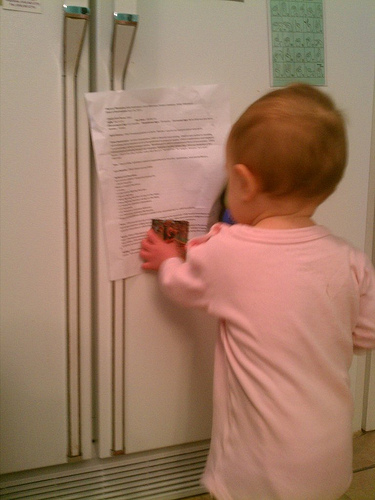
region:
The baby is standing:
[193, 141, 368, 462]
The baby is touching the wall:
[147, 199, 254, 294]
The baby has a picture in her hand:
[145, 218, 181, 263]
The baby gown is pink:
[265, 296, 338, 431]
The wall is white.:
[13, 245, 45, 434]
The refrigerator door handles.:
[57, 7, 149, 49]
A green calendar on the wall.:
[265, 14, 334, 90]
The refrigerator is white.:
[20, 124, 95, 342]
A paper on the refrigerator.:
[74, 95, 224, 222]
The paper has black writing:
[118, 105, 218, 169]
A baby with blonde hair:
[228, 102, 360, 222]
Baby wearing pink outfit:
[162, 228, 372, 437]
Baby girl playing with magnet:
[136, 75, 373, 422]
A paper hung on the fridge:
[80, 101, 208, 279]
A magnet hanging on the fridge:
[130, 165, 209, 279]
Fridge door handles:
[55, 13, 127, 313]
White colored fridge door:
[3, 295, 170, 445]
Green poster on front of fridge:
[269, 2, 334, 87]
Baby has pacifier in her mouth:
[206, 165, 247, 228]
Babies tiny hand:
[131, 226, 208, 309]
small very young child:
[162, 72, 373, 492]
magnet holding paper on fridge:
[144, 201, 201, 267]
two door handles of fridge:
[56, 0, 140, 108]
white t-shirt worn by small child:
[177, 225, 374, 497]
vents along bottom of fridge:
[66, 413, 214, 499]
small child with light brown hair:
[219, 79, 356, 219]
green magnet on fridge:
[265, 0, 339, 88]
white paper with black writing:
[86, 80, 242, 290]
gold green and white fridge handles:
[59, 2, 157, 76]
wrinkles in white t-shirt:
[215, 321, 298, 415]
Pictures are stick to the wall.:
[260, 17, 351, 62]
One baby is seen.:
[171, 114, 353, 348]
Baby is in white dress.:
[190, 270, 342, 469]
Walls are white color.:
[25, 295, 132, 406]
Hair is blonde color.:
[251, 105, 327, 184]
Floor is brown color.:
[351, 435, 368, 483]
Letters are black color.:
[105, 102, 206, 222]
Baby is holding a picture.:
[143, 213, 188, 265]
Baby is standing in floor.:
[210, 270, 330, 495]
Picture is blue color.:
[268, 14, 335, 82]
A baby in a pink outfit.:
[115, 64, 374, 484]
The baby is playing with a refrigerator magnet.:
[110, 78, 366, 433]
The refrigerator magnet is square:
[138, 199, 208, 305]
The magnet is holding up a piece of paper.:
[25, 41, 264, 343]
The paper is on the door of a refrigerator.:
[10, 5, 221, 373]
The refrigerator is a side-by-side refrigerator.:
[27, 7, 190, 462]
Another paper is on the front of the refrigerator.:
[215, 2, 360, 90]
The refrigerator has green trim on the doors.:
[46, 5, 177, 82]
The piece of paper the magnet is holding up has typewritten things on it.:
[65, 77, 253, 314]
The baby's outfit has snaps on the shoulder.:
[69, 30, 373, 372]